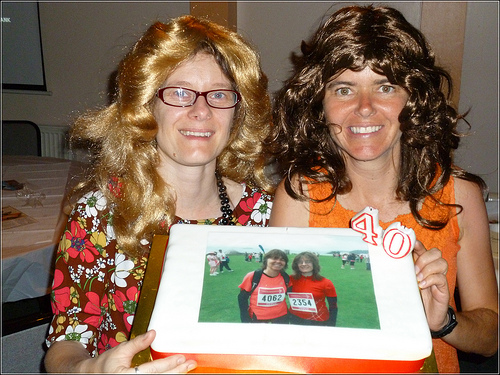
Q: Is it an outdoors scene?
A: Yes, it is outdoors.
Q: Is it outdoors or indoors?
A: It is outdoors.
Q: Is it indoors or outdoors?
A: It is outdoors.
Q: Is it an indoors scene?
A: No, it is outdoors.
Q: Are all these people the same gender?
A: Yes, all the people are female.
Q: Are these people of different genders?
A: No, all the people are female.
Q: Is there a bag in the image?
A: No, there are no bags.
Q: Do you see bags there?
A: No, there are no bags.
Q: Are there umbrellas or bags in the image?
A: No, there are no bags or umbrellas.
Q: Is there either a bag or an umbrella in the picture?
A: No, there are no bags or umbrellas.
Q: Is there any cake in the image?
A: Yes, there is a cake.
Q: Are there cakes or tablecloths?
A: Yes, there is a cake.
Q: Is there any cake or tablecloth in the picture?
A: Yes, there is a cake.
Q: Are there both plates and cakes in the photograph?
A: No, there is a cake but no plates.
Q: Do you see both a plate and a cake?
A: No, there is a cake but no plates.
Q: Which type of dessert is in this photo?
A: The dessert is a cake.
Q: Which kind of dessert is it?
A: The dessert is a cake.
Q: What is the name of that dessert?
A: This is a cake.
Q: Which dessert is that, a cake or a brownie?
A: This is a cake.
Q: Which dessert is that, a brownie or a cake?
A: This is a cake.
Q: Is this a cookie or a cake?
A: This is a cake.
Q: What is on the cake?
A: The number is on the cake.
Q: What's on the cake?
A: The number is on the cake.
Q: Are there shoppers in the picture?
A: No, there are no shoppers.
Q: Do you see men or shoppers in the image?
A: No, there are no shoppers or men.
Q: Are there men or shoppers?
A: No, there are no shoppers or men.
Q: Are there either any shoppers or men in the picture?
A: No, there are no shoppers or men.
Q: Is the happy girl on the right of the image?
A: Yes, the girl is on the right of the image.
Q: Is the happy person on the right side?
A: Yes, the girl is on the right of the image.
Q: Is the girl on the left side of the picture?
A: No, the girl is on the right of the image.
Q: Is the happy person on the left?
A: No, the girl is on the right of the image.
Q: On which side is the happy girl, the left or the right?
A: The girl is on the right of the image.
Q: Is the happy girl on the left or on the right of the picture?
A: The girl is on the right of the image.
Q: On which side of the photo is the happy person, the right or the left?
A: The girl is on the right of the image.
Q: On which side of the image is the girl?
A: The girl is on the right of the image.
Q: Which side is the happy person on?
A: The girl is on the right of the image.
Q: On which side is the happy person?
A: The girl is on the right of the image.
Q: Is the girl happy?
A: Yes, the girl is happy.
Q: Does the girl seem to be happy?
A: Yes, the girl is happy.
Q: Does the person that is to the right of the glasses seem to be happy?
A: Yes, the girl is happy.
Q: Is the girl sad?
A: No, the girl is happy.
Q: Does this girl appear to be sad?
A: No, the girl is happy.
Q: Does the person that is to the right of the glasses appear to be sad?
A: No, the girl is happy.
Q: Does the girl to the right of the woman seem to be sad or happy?
A: The girl is happy.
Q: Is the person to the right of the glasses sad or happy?
A: The girl is happy.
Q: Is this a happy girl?
A: Yes, this is a happy girl.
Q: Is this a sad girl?
A: No, this is a happy girl.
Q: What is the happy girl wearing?
A: The girl is wearing a dress.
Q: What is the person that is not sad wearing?
A: The girl is wearing a dress.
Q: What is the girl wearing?
A: The girl is wearing a dress.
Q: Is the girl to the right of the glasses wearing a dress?
A: Yes, the girl is wearing a dress.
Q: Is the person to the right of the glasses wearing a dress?
A: Yes, the girl is wearing a dress.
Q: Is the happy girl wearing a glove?
A: No, the girl is wearing a dress.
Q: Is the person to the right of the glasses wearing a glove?
A: No, the girl is wearing a dress.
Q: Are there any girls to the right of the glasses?
A: Yes, there is a girl to the right of the glasses.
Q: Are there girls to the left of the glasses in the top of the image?
A: No, the girl is to the right of the glasses.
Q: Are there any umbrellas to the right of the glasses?
A: No, there is a girl to the right of the glasses.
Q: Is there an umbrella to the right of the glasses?
A: No, there is a girl to the right of the glasses.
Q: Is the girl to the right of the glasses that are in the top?
A: Yes, the girl is to the right of the glasses.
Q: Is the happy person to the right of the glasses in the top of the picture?
A: Yes, the girl is to the right of the glasses.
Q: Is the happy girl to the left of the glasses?
A: No, the girl is to the right of the glasses.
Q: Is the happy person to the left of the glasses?
A: No, the girl is to the right of the glasses.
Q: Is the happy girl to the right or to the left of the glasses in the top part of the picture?
A: The girl is to the right of the glasses.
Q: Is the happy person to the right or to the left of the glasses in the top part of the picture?
A: The girl is to the right of the glasses.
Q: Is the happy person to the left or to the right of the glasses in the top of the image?
A: The girl is to the right of the glasses.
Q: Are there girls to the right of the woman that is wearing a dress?
A: Yes, there is a girl to the right of the woman.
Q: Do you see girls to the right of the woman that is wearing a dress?
A: Yes, there is a girl to the right of the woman.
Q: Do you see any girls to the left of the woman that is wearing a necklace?
A: No, the girl is to the right of the woman.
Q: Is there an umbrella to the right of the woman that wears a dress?
A: No, there is a girl to the right of the woman.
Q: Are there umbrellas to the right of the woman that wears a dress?
A: No, there is a girl to the right of the woman.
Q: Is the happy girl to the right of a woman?
A: Yes, the girl is to the right of a woman.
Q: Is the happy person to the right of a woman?
A: Yes, the girl is to the right of a woman.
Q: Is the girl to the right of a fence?
A: No, the girl is to the right of a woman.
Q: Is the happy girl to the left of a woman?
A: No, the girl is to the right of a woman.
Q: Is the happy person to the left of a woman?
A: No, the girl is to the right of a woman.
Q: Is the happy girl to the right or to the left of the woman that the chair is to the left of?
A: The girl is to the right of the woman.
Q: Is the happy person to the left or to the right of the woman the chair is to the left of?
A: The girl is to the right of the woman.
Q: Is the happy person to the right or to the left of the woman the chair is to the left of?
A: The girl is to the right of the woman.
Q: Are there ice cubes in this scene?
A: No, there are no ice cubes.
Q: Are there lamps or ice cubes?
A: No, there are no ice cubes or lamps.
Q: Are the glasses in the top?
A: Yes, the glasses are in the top of the image.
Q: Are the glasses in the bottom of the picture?
A: No, the glasses are in the top of the image.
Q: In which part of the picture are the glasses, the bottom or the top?
A: The glasses are in the top of the image.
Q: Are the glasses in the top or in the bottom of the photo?
A: The glasses are in the top of the image.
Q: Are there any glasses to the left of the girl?
A: Yes, there are glasses to the left of the girl.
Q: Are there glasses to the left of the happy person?
A: Yes, there are glasses to the left of the girl.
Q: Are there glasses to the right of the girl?
A: No, the glasses are to the left of the girl.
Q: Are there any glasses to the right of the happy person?
A: No, the glasses are to the left of the girl.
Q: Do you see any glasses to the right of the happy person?
A: No, the glasses are to the left of the girl.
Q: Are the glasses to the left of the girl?
A: Yes, the glasses are to the left of the girl.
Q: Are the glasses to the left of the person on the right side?
A: Yes, the glasses are to the left of the girl.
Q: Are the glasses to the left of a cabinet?
A: No, the glasses are to the left of the girl.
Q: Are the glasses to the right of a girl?
A: No, the glasses are to the left of a girl.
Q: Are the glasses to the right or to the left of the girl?
A: The glasses are to the left of the girl.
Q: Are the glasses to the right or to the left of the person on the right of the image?
A: The glasses are to the left of the girl.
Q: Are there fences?
A: No, there are no fences.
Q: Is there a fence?
A: No, there are no fences.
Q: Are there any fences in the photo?
A: No, there are no fences.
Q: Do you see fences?
A: No, there are no fences.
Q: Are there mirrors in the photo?
A: No, there are no mirrors.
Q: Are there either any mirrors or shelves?
A: No, there are no mirrors or shelves.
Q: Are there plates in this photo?
A: No, there are no plates.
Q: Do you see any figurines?
A: No, there are no figurines.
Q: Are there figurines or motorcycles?
A: No, there are no figurines or motorcycles.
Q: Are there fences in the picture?
A: No, there are no fences.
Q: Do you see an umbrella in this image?
A: No, there are no umbrellas.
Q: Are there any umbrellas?
A: No, there are no umbrellas.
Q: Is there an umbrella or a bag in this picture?
A: No, there are no umbrellas or bags.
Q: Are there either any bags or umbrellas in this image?
A: No, there are no umbrellas or bags.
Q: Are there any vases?
A: No, there are no vases.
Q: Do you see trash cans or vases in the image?
A: No, there are no vases or trash cans.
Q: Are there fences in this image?
A: No, there are no fences.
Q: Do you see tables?
A: Yes, there is a table.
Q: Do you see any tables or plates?
A: Yes, there is a table.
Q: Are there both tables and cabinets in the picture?
A: No, there is a table but no cabinets.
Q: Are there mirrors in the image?
A: No, there are no mirrors.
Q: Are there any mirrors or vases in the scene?
A: No, there are no mirrors or vases.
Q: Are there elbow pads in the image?
A: No, there are no elbow pads.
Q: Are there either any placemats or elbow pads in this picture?
A: No, there are no elbow pads or placemats.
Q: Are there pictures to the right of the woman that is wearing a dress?
A: Yes, there is a picture to the right of the woman.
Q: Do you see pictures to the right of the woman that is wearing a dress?
A: Yes, there is a picture to the right of the woman.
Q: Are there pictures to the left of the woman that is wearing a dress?
A: No, the picture is to the right of the woman.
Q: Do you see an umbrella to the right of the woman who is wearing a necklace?
A: No, there is a picture to the right of the woman.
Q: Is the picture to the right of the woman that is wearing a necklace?
A: Yes, the picture is to the right of the woman.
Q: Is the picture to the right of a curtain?
A: No, the picture is to the right of the woman.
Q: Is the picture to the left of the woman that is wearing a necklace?
A: No, the picture is to the right of the woman.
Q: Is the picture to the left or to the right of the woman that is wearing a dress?
A: The picture is to the right of the woman.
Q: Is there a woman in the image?
A: Yes, there is a woman.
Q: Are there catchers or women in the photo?
A: Yes, there is a woman.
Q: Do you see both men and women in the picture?
A: No, there is a woman but no men.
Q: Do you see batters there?
A: No, there are no batters.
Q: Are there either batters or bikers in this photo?
A: No, there are no batters or bikers.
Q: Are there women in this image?
A: Yes, there is a woman.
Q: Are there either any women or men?
A: Yes, there is a woman.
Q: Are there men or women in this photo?
A: Yes, there is a woman.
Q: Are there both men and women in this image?
A: No, there is a woman but no men.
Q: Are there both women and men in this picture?
A: No, there is a woman but no men.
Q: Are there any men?
A: No, there are no men.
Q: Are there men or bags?
A: No, there are no men or bags.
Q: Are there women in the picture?
A: Yes, there is a woman.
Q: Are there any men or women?
A: Yes, there is a woman.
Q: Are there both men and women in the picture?
A: No, there is a woman but no men.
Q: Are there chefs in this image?
A: No, there are no chefs.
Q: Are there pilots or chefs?
A: No, there are no chefs or pilots.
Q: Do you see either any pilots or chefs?
A: No, there are no chefs or pilots.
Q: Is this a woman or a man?
A: This is a woman.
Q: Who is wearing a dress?
A: The woman is wearing a dress.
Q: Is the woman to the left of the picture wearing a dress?
A: Yes, the woman is wearing a dress.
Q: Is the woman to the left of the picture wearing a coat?
A: No, the woman is wearing a dress.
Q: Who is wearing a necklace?
A: The woman is wearing a necklace.